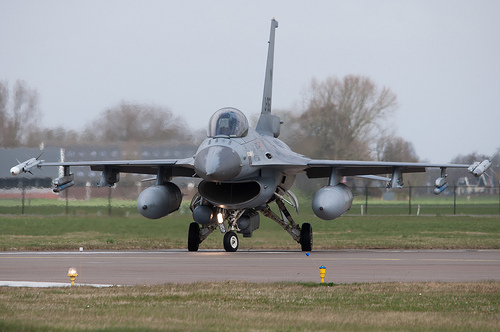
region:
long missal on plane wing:
[129, 183, 186, 221]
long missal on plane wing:
[47, 169, 77, 199]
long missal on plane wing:
[433, 178, 448, 196]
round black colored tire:
[186, 220, 202, 252]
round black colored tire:
[219, 225, 242, 253]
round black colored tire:
[301, 218, 316, 254]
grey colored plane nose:
[193, 146, 238, 184]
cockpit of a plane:
[185, 83, 263, 190]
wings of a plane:
[306, 109, 498, 246]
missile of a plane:
[310, 169, 355, 223]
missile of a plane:
[119, 173, 194, 224]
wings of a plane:
[0, 131, 201, 191]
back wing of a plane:
[252, 11, 296, 141]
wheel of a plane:
[217, 225, 244, 250]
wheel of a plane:
[173, 211, 207, 258]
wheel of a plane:
[292, 215, 316, 256]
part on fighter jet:
[214, 223, 244, 254]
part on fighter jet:
[289, 205, 322, 250]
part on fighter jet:
[173, 210, 213, 252]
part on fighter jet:
[306, 155, 358, 229]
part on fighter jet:
[121, 161, 194, 223]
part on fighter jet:
[5, 135, 54, 187]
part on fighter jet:
[420, 160, 457, 201]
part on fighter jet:
[246, 13, 291, 144]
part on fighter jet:
[201, 83, 263, 151]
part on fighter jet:
[178, 124, 247, 199]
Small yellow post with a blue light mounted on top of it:
[316, 263, 329, 285]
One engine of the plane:
[300, 173, 363, 228]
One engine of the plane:
[129, 180, 185, 222]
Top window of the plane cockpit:
[203, 98, 253, 140]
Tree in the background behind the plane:
[295, 68, 411, 163]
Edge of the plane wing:
[10, 148, 47, 186]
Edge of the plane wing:
[452, 147, 499, 191]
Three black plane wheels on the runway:
[165, 213, 330, 260]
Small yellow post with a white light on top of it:
[64, 264, 81, 289]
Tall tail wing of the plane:
[251, 13, 288, 129]